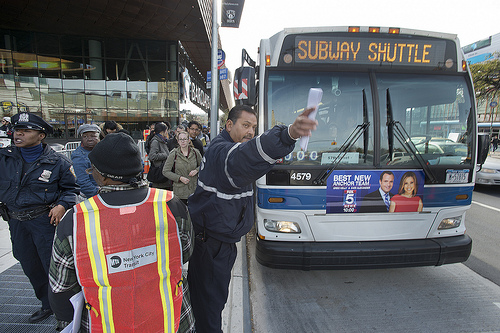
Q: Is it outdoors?
A: Yes, it is outdoors.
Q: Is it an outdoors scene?
A: Yes, it is outdoors.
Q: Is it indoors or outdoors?
A: It is outdoors.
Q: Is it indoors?
A: No, it is outdoors.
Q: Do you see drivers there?
A: No, there are no drivers.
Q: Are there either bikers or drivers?
A: No, there are no drivers or bikers.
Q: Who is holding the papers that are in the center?
A: The man is holding the papers.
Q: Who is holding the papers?
A: The man is holding the papers.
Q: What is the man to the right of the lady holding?
A: The man is holding the papers.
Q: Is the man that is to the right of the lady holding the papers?
A: Yes, the man is holding the papers.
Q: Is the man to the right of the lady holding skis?
A: No, the man is holding the papers.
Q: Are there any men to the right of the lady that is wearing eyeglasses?
A: Yes, there is a man to the right of the lady.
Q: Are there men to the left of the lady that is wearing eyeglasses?
A: No, the man is to the right of the lady.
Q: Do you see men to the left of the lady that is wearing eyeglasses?
A: No, the man is to the right of the lady.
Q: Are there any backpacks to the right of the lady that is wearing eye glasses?
A: No, there is a man to the right of the lady.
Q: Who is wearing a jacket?
A: The man is wearing a jacket.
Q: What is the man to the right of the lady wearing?
A: The man is wearing a jacket.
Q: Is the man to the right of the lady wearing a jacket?
A: Yes, the man is wearing a jacket.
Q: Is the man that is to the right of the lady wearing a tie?
A: No, the man is wearing a jacket.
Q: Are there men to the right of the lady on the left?
A: Yes, there is a man to the right of the lady.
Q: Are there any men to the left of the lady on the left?
A: No, the man is to the right of the lady.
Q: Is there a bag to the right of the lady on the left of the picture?
A: No, there is a man to the right of the lady.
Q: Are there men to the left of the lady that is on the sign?
A: Yes, there is a man to the left of the lady.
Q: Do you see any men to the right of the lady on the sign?
A: No, the man is to the left of the lady.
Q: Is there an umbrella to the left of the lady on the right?
A: No, there is a man to the left of the lady.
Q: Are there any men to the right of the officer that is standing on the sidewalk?
A: Yes, there is a man to the right of the officer.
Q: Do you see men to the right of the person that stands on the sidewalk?
A: Yes, there is a man to the right of the officer.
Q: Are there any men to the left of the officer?
A: No, the man is to the right of the officer.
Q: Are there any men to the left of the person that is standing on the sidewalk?
A: No, the man is to the right of the officer.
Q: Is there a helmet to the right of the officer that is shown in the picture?
A: No, there is a man to the right of the officer.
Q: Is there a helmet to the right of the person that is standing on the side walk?
A: No, there is a man to the right of the officer.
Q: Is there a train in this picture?
A: No, there are no trains.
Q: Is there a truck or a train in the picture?
A: No, there are no trains or trucks.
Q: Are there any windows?
A: Yes, there is a window.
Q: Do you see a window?
A: Yes, there is a window.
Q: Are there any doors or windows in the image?
A: Yes, there is a window.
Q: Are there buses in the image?
A: Yes, there is a bus.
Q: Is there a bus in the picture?
A: Yes, there is a bus.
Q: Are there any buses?
A: Yes, there is a bus.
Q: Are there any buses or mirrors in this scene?
A: Yes, there is a bus.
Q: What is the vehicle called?
A: The vehicle is a bus.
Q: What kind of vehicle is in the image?
A: The vehicle is a bus.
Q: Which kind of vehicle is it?
A: The vehicle is a bus.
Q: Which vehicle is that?
A: This is a bus.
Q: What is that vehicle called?
A: This is a bus.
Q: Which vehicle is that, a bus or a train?
A: This is a bus.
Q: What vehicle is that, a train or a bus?
A: This is a bus.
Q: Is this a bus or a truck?
A: This is a bus.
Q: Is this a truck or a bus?
A: This is a bus.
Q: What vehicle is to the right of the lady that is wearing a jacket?
A: The vehicle is a bus.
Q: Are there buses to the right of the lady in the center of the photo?
A: Yes, there is a bus to the right of the lady.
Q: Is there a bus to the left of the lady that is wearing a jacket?
A: No, the bus is to the right of the lady.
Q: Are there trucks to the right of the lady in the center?
A: No, there is a bus to the right of the lady.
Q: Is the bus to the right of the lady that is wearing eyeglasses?
A: Yes, the bus is to the right of the lady.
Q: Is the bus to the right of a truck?
A: No, the bus is to the right of the lady.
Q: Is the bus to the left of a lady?
A: No, the bus is to the right of a lady.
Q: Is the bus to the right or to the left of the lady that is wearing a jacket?
A: The bus is to the right of the lady.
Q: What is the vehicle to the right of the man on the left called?
A: The vehicle is a bus.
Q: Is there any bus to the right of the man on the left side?
A: Yes, there is a bus to the right of the man.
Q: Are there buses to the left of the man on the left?
A: No, the bus is to the right of the man.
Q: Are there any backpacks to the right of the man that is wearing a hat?
A: No, there is a bus to the right of the man.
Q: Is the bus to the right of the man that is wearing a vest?
A: Yes, the bus is to the right of the man.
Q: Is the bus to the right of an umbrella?
A: No, the bus is to the right of the man.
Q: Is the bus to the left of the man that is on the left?
A: No, the bus is to the right of the man.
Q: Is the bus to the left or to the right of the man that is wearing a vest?
A: The bus is to the right of the man.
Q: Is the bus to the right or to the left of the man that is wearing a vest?
A: The bus is to the right of the man.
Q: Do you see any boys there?
A: No, there are no boys.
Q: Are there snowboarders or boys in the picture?
A: No, there are no boys or snowboarders.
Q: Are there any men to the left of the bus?
A: Yes, there is a man to the left of the bus.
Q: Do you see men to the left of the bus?
A: Yes, there is a man to the left of the bus.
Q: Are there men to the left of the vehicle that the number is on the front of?
A: Yes, there is a man to the left of the bus.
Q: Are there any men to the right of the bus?
A: No, the man is to the left of the bus.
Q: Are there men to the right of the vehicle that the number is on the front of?
A: No, the man is to the left of the bus.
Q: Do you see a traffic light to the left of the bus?
A: No, there is a man to the left of the bus.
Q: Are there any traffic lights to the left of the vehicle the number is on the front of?
A: No, there is a man to the left of the bus.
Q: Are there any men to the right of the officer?
A: Yes, there is a man to the right of the officer.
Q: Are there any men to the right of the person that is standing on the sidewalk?
A: Yes, there is a man to the right of the officer.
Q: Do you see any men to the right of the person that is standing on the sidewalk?
A: Yes, there is a man to the right of the officer.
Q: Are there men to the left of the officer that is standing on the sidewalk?
A: No, the man is to the right of the officer.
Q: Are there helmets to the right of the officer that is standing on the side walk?
A: No, there is a man to the right of the officer.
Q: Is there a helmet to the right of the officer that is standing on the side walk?
A: No, there is a man to the right of the officer.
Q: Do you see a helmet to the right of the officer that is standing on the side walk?
A: No, there is a man to the right of the officer.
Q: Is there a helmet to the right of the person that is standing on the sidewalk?
A: No, there is a man to the right of the officer.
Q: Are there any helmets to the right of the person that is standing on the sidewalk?
A: No, there is a man to the right of the officer.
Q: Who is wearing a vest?
A: The man is wearing a vest.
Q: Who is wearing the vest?
A: The man is wearing a vest.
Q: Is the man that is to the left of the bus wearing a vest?
A: Yes, the man is wearing a vest.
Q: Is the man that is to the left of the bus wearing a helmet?
A: No, the man is wearing a vest.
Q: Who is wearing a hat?
A: The man is wearing a hat.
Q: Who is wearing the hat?
A: The man is wearing a hat.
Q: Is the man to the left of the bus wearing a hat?
A: Yes, the man is wearing a hat.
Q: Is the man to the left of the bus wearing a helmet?
A: No, the man is wearing a hat.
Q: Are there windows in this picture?
A: Yes, there is a window.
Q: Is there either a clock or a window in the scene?
A: Yes, there is a window.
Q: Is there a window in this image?
A: Yes, there is a window.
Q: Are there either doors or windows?
A: Yes, there is a window.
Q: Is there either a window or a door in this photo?
A: Yes, there is a window.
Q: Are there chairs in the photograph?
A: No, there are no chairs.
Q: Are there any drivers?
A: No, there are no drivers.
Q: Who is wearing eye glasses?
A: The lady is wearing eye glasses.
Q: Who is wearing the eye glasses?
A: The lady is wearing eye glasses.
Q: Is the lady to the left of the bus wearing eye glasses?
A: Yes, the lady is wearing eye glasses.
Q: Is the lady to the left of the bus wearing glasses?
A: No, the lady is wearing eye glasses.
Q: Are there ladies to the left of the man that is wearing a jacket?
A: Yes, there is a lady to the left of the man.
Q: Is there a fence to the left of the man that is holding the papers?
A: No, there is a lady to the left of the man.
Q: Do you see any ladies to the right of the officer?
A: Yes, there is a lady to the right of the officer.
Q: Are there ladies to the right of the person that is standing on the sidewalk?
A: Yes, there is a lady to the right of the officer.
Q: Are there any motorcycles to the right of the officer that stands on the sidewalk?
A: No, there is a lady to the right of the officer.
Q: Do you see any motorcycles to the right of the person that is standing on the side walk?
A: No, there is a lady to the right of the officer.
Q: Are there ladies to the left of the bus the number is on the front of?
A: Yes, there is a lady to the left of the bus.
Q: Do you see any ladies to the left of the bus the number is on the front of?
A: Yes, there is a lady to the left of the bus.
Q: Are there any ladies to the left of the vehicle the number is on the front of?
A: Yes, there is a lady to the left of the bus.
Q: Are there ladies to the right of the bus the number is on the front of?
A: No, the lady is to the left of the bus.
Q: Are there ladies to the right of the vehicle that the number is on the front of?
A: No, the lady is to the left of the bus.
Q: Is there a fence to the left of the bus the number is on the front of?
A: No, there is a lady to the left of the bus.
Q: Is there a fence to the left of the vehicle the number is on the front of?
A: No, there is a lady to the left of the bus.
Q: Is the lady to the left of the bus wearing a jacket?
A: Yes, the lady is wearing a jacket.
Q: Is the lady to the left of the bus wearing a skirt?
A: No, the lady is wearing a jacket.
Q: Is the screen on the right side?
A: Yes, the screen is on the right of the image.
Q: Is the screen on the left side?
A: No, the screen is on the right of the image.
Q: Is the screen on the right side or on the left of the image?
A: The screen is on the right of the image.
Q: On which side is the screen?
A: The screen is on the right of the image.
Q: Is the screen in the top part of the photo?
A: Yes, the screen is in the top of the image.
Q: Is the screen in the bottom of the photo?
A: No, the screen is in the top of the image.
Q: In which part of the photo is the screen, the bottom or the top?
A: The screen is in the top of the image.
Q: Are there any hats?
A: Yes, there is a hat.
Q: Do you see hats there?
A: Yes, there is a hat.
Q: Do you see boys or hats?
A: Yes, there is a hat.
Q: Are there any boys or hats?
A: Yes, there is a hat.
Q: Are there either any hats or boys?
A: Yes, there is a hat.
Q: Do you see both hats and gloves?
A: No, there is a hat but no gloves.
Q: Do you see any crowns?
A: No, there are no crowns.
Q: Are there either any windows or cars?
A: Yes, there is a window.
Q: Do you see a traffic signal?
A: No, there are no traffic lights.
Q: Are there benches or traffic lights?
A: No, there are no traffic lights or benches.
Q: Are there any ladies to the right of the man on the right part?
A: Yes, there is a lady to the right of the man.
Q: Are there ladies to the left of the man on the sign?
A: No, the lady is to the right of the man.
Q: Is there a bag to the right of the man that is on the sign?
A: No, there is a lady to the right of the man.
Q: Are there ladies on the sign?
A: Yes, there is a lady on the sign.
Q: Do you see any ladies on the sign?
A: Yes, there is a lady on the sign.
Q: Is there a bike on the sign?
A: No, there is a lady on the sign.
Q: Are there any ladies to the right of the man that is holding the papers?
A: Yes, there is a lady to the right of the man.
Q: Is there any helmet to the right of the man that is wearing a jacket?
A: No, there is a lady to the right of the man.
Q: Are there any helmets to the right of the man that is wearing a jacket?
A: No, there is a lady to the right of the man.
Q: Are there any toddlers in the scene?
A: No, there are no toddlers.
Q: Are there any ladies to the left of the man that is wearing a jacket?
A: Yes, there is a lady to the left of the man.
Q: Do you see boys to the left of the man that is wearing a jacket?
A: No, there is a lady to the left of the man.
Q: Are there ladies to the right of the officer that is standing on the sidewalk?
A: Yes, there is a lady to the right of the officer.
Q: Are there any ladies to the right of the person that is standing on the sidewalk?
A: Yes, there is a lady to the right of the officer.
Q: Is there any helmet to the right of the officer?
A: No, there is a lady to the right of the officer.